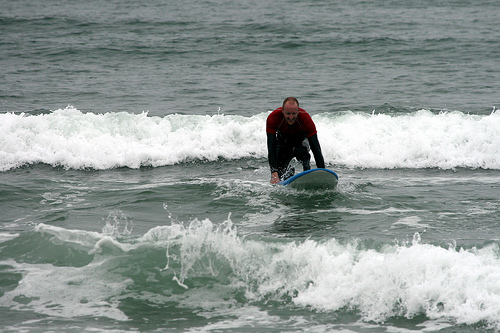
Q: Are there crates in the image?
A: No, there are no crates.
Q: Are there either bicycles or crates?
A: No, there are no crates or bicycles.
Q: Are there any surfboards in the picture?
A: Yes, there is a surfboard.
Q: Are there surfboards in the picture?
A: Yes, there is a surfboard.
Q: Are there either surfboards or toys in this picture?
A: Yes, there is a surfboard.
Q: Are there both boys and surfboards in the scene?
A: No, there is a surfboard but no boys.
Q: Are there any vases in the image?
A: No, there are no vases.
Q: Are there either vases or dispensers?
A: No, there are no vases or dispensers.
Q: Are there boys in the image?
A: No, there are no boys.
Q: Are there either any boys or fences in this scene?
A: No, there are no boys or fences.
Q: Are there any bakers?
A: No, there are no bakers.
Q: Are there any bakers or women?
A: No, there are no bakers or women.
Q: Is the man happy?
A: Yes, the man is happy.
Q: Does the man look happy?
A: Yes, the man is happy.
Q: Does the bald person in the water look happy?
A: Yes, the man is happy.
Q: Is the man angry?
A: No, the man is happy.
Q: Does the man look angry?
A: No, the man is happy.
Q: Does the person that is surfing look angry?
A: No, the man is happy.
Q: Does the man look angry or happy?
A: The man is happy.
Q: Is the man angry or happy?
A: The man is happy.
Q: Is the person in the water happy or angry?
A: The man is happy.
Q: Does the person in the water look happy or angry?
A: The man is happy.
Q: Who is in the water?
A: The man is in the water.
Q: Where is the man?
A: The man is in the water.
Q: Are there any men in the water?
A: Yes, there is a man in the water.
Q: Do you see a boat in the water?
A: No, there is a man in the water.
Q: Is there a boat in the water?
A: No, there is a man in the water.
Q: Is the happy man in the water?
A: Yes, the man is in the water.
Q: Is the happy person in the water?
A: Yes, the man is in the water.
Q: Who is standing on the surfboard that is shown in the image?
A: The man is standing on the surfboard.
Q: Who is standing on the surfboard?
A: The man is standing on the surfboard.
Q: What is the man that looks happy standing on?
A: The man is standing on the surfboard.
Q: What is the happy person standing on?
A: The man is standing on the surfboard.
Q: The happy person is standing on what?
A: The man is standing on the surfboard.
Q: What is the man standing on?
A: The man is standing on the surfboard.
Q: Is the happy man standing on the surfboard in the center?
A: Yes, the man is standing on the surfboard.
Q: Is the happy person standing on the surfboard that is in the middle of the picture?
A: Yes, the man is standing on the surfboard.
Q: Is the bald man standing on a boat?
A: No, the man is standing on the surfboard.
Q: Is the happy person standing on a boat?
A: No, the man is standing on the surfboard.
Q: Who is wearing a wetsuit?
A: The man is wearing a wetsuit.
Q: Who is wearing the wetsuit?
A: The man is wearing a wetsuit.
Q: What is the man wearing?
A: The man is wearing a wetsuit.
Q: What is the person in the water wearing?
A: The man is wearing a wetsuit.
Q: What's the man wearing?
A: The man is wearing a wetsuit.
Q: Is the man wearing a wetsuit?
A: Yes, the man is wearing a wetsuit.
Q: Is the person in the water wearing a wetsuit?
A: Yes, the man is wearing a wetsuit.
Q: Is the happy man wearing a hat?
A: No, the man is wearing a wetsuit.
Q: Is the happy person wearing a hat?
A: No, the man is wearing a wetsuit.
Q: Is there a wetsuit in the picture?
A: Yes, there is a wetsuit.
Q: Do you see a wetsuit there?
A: Yes, there is a wetsuit.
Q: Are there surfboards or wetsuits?
A: Yes, there is a wetsuit.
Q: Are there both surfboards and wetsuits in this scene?
A: Yes, there are both a wetsuit and a surfboard.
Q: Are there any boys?
A: No, there are no boys.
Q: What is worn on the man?
A: The wetsuit is worn on the man.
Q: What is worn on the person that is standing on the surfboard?
A: The wetsuit is worn on the man.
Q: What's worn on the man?
A: The wetsuit is worn on the man.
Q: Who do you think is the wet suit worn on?
A: The wet suit is worn on the man.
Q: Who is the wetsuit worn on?
A: The wet suit is worn on the man.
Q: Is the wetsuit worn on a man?
A: Yes, the wetsuit is worn on a man.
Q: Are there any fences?
A: No, there are no fences.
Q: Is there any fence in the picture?
A: No, there are no fences.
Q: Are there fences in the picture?
A: No, there are no fences.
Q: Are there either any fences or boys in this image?
A: No, there are no fences or boys.